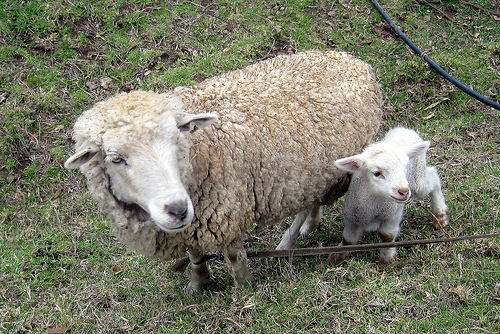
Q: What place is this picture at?
A: It is at the field.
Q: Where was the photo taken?
A: It was taken at the field.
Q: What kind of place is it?
A: It is a field.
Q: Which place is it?
A: It is a field.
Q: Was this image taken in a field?
A: Yes, it was taken in a field.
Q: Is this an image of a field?
A: Yes, it is showing a field.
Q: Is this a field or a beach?
A: It is a field.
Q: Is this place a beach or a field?
A: It is a field.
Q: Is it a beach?
A: No, it is a field.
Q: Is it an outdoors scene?
A: Yes, it is outdoors.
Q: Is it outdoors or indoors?
A: It is outdoors.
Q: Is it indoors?
A: No, it is outdoors.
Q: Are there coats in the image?
A: Yes, there is a coat.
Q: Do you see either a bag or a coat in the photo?
A: Yes, there is a coat.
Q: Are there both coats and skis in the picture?
A: No, there is a coat but no skis.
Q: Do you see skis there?
A: No, there are no skis.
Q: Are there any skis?
A: No, there are no skis.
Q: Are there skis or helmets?
A: No, there are no skis or helmets.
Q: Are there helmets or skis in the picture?
A: No, there are no skis or helmets.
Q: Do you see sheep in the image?
A: Yes, there is a sheep.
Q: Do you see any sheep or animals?
A: Yes, there is a sheep.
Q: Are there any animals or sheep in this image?
A: Yes, there is a sheep.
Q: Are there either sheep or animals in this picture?
A: Yes, there is a sheep.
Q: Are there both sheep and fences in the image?
A: No, there is a sheep but no fences.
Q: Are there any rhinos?
A: No, there are no rhinos.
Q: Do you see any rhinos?
A: No, there are no rhinos.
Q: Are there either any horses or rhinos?
A: No, there are no rhinos or horses.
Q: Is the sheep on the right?
A: Yes, the sheep is on the right of the image.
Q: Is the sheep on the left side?
A: No, the sheep is on the right of the image.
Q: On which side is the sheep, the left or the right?
A: The sheep is on the right of the image.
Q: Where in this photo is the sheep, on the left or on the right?
A: The sheep is on the right of the image.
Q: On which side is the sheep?
A: The sheep is on the right of the image.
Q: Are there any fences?
A: No, there are no fences.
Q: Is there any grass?
A: Yes, there is grass.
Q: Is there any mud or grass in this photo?
A: Yes, there is grass.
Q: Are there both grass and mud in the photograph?
A: No, there is grass but no mud.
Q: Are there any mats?
A: No, there are no mats.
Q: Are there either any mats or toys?
A: No, there are no mats or toys.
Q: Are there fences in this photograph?
A: No, there are no fences.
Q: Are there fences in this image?
A: No, there are no fences.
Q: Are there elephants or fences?
A: No, there are no fences or elephants.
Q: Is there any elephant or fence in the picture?
A: No, there are no fences or elephants.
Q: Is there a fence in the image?
A: No, there are no fences.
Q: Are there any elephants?
A: No, there are no elephants.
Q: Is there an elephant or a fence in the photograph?
A: No, there are no elephants or fences.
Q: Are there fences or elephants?
A: No, there are no elephants or fences.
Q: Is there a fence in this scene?
A: No, there are no fences.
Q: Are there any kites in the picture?
A: No, there are no kites.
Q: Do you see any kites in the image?
A: No, there are no kites.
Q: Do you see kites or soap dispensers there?
A: No, there are no kites or soap dispensers.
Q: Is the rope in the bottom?
A: Yes, the rope is in the bottom of the image.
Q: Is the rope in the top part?
A: No, the rope is in the bottom of the image.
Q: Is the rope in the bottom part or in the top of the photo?
A: The rope is in the bottom of the image.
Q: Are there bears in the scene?
A: No, there are no bears.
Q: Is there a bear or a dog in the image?
A: No, there are no bears or dogs.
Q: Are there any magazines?
A: No, there are no magazines.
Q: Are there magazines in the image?
A: No, there are no magazines.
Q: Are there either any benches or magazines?
A: No, there are no magazines or benches.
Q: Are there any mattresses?
A: No, there are no mattresses.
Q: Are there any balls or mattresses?
A: No, there are no mattresses or balls.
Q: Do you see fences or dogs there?
A: No, there are no fences or dogs.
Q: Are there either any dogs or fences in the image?
A: No, there are no fences or dogs.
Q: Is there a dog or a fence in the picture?
A: No, there are no fences or dogs.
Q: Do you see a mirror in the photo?
A: No, there are no mirrors.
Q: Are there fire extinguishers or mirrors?
A: No, there are no mirrors or fire extinguishers.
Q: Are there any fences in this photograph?
A: No, there are no fences.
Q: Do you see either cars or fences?
A: No, there are no fences or cars.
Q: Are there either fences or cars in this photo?
A: No, there are no fences or cars.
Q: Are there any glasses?
A: No, there are no glasses.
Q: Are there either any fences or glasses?
A: No, there are no glasses or fences.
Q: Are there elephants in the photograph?
A: No, there are no elephants.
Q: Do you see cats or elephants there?
A: No, there are no elephants or cats.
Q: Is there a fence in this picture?
A: No, there are no fences.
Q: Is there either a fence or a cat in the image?
A: No, there are no fences or cats.